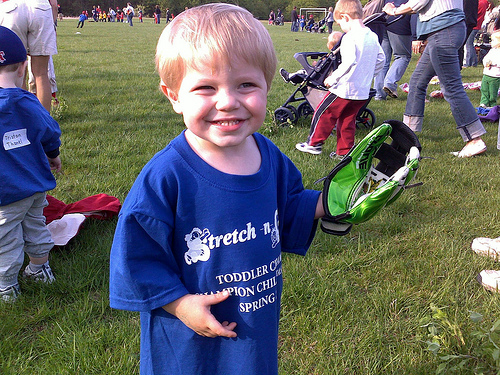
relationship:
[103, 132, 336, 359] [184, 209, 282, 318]
shirt with lettering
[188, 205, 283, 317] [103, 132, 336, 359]
letters on shirt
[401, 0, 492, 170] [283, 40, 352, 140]
woman pushing stroller